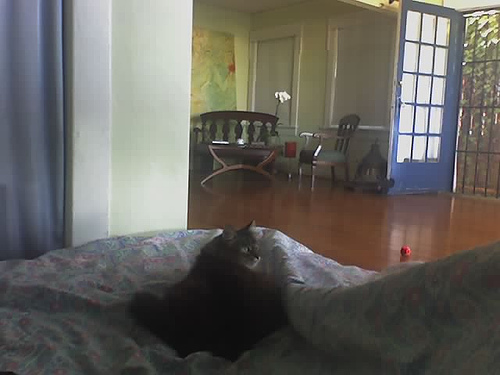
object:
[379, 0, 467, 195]
blue door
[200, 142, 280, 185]
coffee table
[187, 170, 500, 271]
ground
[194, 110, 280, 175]
bench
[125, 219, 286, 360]
cat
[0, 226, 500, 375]
bed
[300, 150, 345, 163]
seat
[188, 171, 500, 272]
floor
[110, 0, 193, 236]
wall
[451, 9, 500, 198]
bars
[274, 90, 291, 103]
flower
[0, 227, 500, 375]
grey blanket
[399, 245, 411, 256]
ball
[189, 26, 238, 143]
painting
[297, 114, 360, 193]
chair